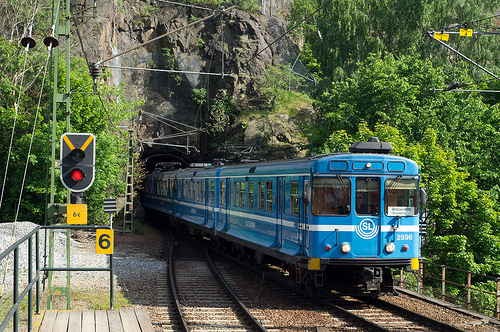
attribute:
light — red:
[72, 169, 82, 179]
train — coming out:
[226, 144, 416, 293]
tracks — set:
[247, 252, 470, 330]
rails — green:
[4, 224, 119, 329]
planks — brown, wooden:
[61, 306, 143, 330]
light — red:
[60, 133, 95, 191]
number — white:
[395, 232, 413, 240]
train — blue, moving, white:
[152, 139, 426, 294]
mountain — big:
[4, 0, 497, 223]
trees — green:
[293, 58, 498, 268]